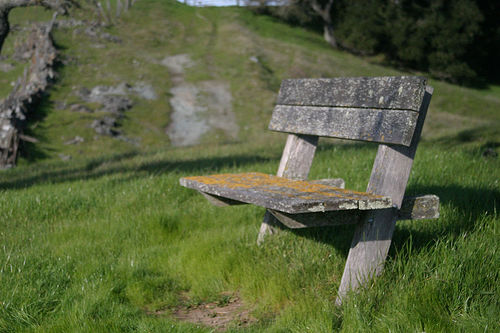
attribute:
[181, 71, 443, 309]
bench — old, antique, dirty, wooden, grey, rusted, yellow, small, orange, worn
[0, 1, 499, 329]
field — growing, indented, grassy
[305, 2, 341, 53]
tree — blurry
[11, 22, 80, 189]
wall — rock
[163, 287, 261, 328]
spot — bare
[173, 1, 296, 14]
sky — blue